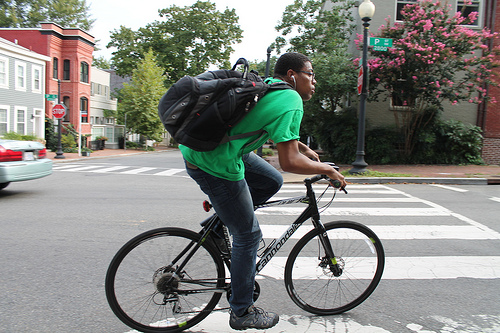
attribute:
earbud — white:
[274, 64, 335, 111]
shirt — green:
[196, 77, 312, 187]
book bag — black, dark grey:
[158, 63, 276, 150]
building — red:
[1, 20, 95, 155]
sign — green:
[362, 34, 400, 52]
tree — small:
[369, 3, 490, 173]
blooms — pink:
[355, 0, 491, 99]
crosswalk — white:
[236, 171, 498, 331]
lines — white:
[360, 179, 469, 278]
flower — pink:
[457, 11, 463, 20]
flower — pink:
[464, 4, 481, 24]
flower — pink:
[347, 29, 364, 50]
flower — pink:
[416, 11, 428, 26]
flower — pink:
[402, 38, 414, 48]